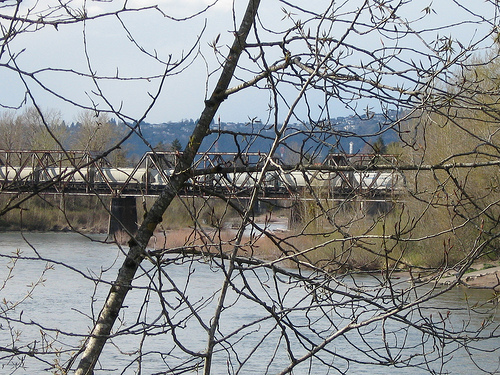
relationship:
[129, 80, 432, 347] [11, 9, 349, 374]
branches of tree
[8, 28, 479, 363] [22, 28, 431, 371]
branches on tree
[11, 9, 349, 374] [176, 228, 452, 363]
tree with branch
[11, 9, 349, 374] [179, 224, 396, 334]
tree with branch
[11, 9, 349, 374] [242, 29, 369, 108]
tree with branch